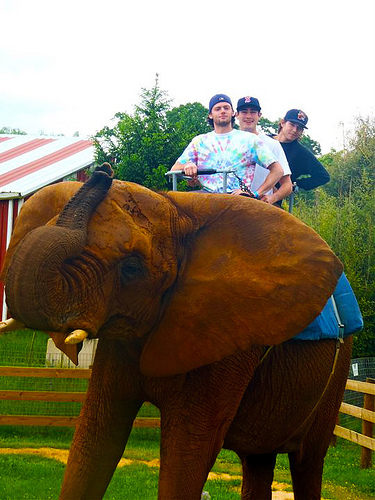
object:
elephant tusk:
[64, 329, 88, 344]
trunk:
[7, 162, 116, 338]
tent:
[0, 134, 99, 202]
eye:
[121, 253, 144, 280]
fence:
[332, 378, 375, 454]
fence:
[0, 364, 375, 468]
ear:
[138, 194, 344, 377]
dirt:
[0, 444, 375, 499]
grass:
[0, 328, 375, 497]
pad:
[296, 273, 364, 340]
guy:
[169, 93, 329, 201]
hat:
[282, 109, 309, 132]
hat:
[234, 95, 259, 113]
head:
[279, 109, 309, 141]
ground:
[342, 406, 363, 423]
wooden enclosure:
[19, 180, 357, 285]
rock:
[198, 477, 206, 498]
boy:
[171, 93, 305, 209]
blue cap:
[208, 91, 234, 114]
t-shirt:
[173, 130, 292, 196]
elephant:
[3, 174, 364, 499]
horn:
[64, 330, 87, 344]